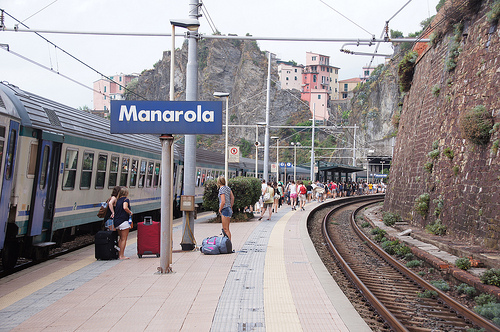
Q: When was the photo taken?
A: Daytime.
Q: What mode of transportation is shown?
A: Train.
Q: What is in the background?
A: Buildings.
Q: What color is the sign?
A: Blue.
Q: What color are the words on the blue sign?
A: White.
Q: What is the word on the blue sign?
A: Manarola.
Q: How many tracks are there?
A: Two.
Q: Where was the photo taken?
A: At the train station.